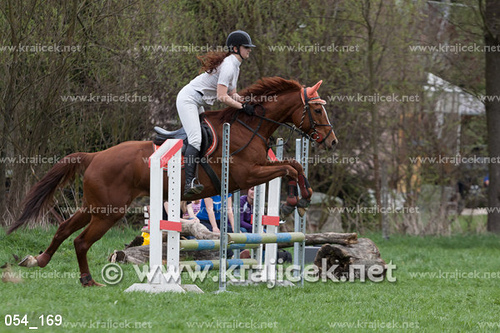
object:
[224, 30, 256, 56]
helmet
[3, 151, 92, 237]
horse tail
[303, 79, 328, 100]
cover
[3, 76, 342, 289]
horse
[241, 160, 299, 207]
legs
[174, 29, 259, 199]
girl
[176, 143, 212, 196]
boots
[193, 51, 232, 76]
hair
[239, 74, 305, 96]
mane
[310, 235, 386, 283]
log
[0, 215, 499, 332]
ground